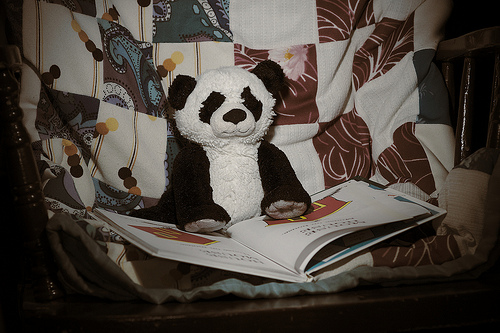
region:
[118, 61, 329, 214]
Teddy bear reading a book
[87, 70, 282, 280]
Teddy bear with a book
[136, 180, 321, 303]
book in front of teddy bear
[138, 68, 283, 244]
teddy bear in a chair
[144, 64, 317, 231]
Black and white teddy bear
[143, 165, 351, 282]
Book in front of a teddy bear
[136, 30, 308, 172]
White and black teddy bear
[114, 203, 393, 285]
Book in front of a bear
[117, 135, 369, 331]
teddy bear with a book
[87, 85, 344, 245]
Bear in a chair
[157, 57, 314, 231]
a stuffed panda bear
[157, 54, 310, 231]
the black and white stuffed panda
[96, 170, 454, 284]
the book under the stuffed animals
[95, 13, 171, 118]
a patch sewn on the back of the couch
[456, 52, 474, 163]
a wooden brace on the chairs arm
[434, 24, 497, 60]
the wooden arm of the chair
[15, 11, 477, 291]
a folded blanket on the chair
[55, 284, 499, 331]
the brown wooden seat of the chair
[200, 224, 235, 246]
the panda hands shadow on the book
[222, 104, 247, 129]
the black nose of the panda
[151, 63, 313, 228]
stuffed panda on blanket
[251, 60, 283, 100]
ear of the panda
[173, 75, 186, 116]
ear of the panda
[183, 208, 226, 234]
paw of the panda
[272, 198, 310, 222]
paw of the panda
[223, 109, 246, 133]
nose of the panda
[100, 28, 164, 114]
quilt square on blanket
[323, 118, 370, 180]
quilt square on blanket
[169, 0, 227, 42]
quilt square on blanket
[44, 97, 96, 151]
quilt square on blanket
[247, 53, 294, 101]
ear of stuffed animal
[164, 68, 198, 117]
ear of stuffed animal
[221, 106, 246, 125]
black nose of stuffed animal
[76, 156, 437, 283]
book with cover open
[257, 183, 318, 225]
foot of stuffed animal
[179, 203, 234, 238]
foot of stuffed animal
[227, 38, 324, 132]
square on a quilt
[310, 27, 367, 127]
square on a quilt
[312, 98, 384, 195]
square on a quilt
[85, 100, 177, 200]
square on a quilt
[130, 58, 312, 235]
A black and white bear.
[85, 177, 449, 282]
A large book in front of a bear.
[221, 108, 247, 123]
Black nose of a bear.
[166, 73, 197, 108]
Left side black ear of a bear.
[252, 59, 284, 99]
Right side black ear of a bear.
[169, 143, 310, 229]
Black and white arms of a bear.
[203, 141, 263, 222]
White down the middle of a bears chest.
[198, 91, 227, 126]
Black around a bears left side eye.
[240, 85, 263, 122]
Black around a bears right side eye.